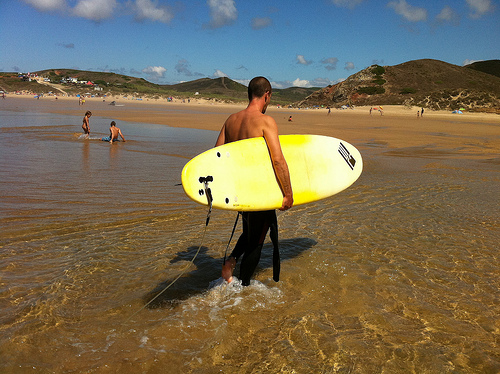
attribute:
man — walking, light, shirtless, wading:
[214, 76, 294, 285]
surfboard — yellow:
[176, 133, 365, 213]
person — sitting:
[94, 121, 130, 145]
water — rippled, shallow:
[3, 111, 499, 370]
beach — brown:
[0, 90, 500, 161]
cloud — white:
[129, 0, 176, 30]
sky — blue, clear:
[0, 1, 499, 91]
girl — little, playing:
[82, 110, 92, 135]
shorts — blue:
[100, 134, 115, 144]